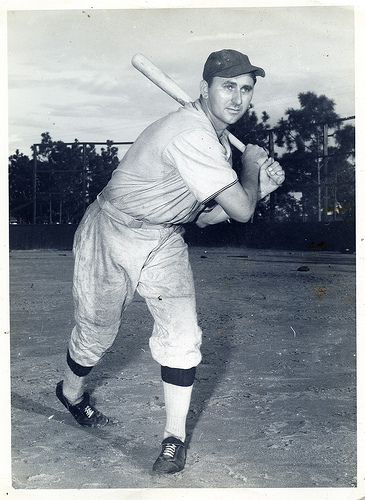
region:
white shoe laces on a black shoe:
[162, 440, 178, 459]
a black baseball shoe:
[152, 436, 187, 473]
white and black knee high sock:
[160, 363, 194, 443]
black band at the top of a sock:
[158, 363, 195, 388]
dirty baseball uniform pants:
[68, 196, 204, 368]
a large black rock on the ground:
[296, 263, 311, 269]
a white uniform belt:
[97, 194, 179, 233]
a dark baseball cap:
[201, 46, 269, 81]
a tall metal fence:
[31, 116, 353, 251]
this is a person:
[60, 29, 285, 480]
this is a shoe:
[143, 424, 191, 479]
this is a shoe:
[47, 368, 120, 433]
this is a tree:
[14, 147, 68, 250]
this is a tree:
[42, 131, 85, 242]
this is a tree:
[278, 90, 344, 255]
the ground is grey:
[268, 357, 314, 423]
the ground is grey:
[270, 289, 319, 350]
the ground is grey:
[18, 281, 53, 339]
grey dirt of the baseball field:
[257, 313, 324, 415]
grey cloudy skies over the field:
[50, 43, 106, 109]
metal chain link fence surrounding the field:
[306, 127, 347, 231]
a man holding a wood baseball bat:
[61, 40, 308, 294]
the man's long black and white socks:
[36, 338, 222, 461]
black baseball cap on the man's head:
[198, 45, 269, 95]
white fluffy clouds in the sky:
[34, 32, 130, 112]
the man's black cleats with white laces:
[51, 375, 193, 477]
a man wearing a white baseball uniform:
[56, 46, 285, 471]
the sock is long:
[159, 389, 201, 435]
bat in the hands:
[113, 42, 284, 180]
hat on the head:
[205, 41, 272, 76]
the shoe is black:
[157, 463, 174, 474]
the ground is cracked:
[257, 375, 321, 464]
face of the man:
[209, 77, 253, 128]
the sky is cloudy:
[22, 46, 129, 125]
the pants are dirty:
[68, 236, 112, 342]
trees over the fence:
[306, 124, 347, 226]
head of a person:
[185, 41, 267, 126]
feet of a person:
[37, 381, 112, 444]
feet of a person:
[135, 410, 205, 479]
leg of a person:
[133, 278, 227, 418]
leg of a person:
[50, 276, 137, 387]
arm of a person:
[206, 155, 271, 230]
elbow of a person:
[221, 203, 275, 241]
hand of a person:
[234, 132, 277, 178]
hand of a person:
[250, 149, 296, 198]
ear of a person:
[192, 65, 219, 102]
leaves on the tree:
[300, 107, 325, 137]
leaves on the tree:
[312, 188, 327, 200]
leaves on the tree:
[299, 161, 314, 184]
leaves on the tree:
[336, 147, 357, 180]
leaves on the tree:
[48, 158, 69, 179]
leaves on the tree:
[76, 151, 90, 164]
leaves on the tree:
[37, 121, 52, 155]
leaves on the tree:
[102, 136, 115, 166]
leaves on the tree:
[24, 164, 37, 197]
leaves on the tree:
[234, 114, 270, 145]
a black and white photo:
[44, 69, 343, 256]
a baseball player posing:
[15, 49, 356, 307]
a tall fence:
[7, 113, 364, 240]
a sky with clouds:
[5, 14, 362, 145]